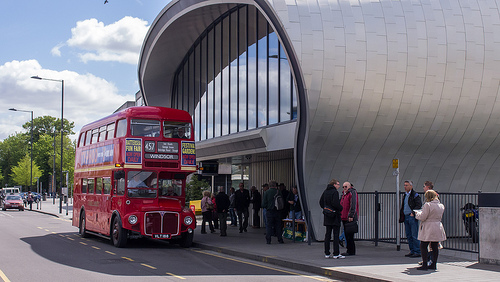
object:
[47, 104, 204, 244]
bus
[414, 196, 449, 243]
jacket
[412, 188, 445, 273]
woman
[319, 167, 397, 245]
woman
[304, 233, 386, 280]
sidewalk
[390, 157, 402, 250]
pole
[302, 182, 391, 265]
people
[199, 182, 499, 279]
sidewalk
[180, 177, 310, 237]
people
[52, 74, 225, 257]
bus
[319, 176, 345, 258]
person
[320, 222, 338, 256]
dark pants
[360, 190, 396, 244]
fence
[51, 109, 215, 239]
bus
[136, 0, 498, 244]
building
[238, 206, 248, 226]
pants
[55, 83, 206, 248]
bus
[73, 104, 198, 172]
upper level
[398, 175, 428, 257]
person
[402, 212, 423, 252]
pants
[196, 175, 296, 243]
people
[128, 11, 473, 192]
building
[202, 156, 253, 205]
entrance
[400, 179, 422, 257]
man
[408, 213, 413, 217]
hand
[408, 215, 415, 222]
pocket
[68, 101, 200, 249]
bus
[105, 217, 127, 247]
wheel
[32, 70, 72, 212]
light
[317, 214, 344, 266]
pants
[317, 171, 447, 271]
men/women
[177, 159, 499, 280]
bus stop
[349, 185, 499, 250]
fence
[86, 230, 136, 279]
lines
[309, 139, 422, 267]
bus stop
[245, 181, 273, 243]
person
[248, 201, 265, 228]
pants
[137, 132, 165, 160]
front number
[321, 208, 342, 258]
dark pants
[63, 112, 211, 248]
bus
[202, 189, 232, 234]
person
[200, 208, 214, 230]
pants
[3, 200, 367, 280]
street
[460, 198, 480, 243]
motorcycle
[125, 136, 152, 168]
bus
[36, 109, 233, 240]
bus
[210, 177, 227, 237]
person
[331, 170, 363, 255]
person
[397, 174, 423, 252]
person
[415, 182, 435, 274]
person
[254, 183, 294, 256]
person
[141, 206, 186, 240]
grill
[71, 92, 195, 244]
two stories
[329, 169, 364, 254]
jacket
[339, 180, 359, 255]
man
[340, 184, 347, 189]
sunglasses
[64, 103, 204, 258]
bus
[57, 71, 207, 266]
bus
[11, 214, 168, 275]
street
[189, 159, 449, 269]
people